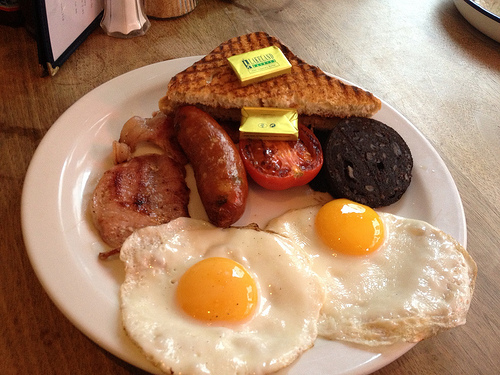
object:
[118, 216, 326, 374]
eggs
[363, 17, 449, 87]
liquer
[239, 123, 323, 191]
tomato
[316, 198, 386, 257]
yellow yolk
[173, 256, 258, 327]
yellow yolk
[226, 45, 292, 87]
butter packet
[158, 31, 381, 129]
bread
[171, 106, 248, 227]
sausage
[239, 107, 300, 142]
butter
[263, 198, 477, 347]
egg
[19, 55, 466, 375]
plate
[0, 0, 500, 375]
table